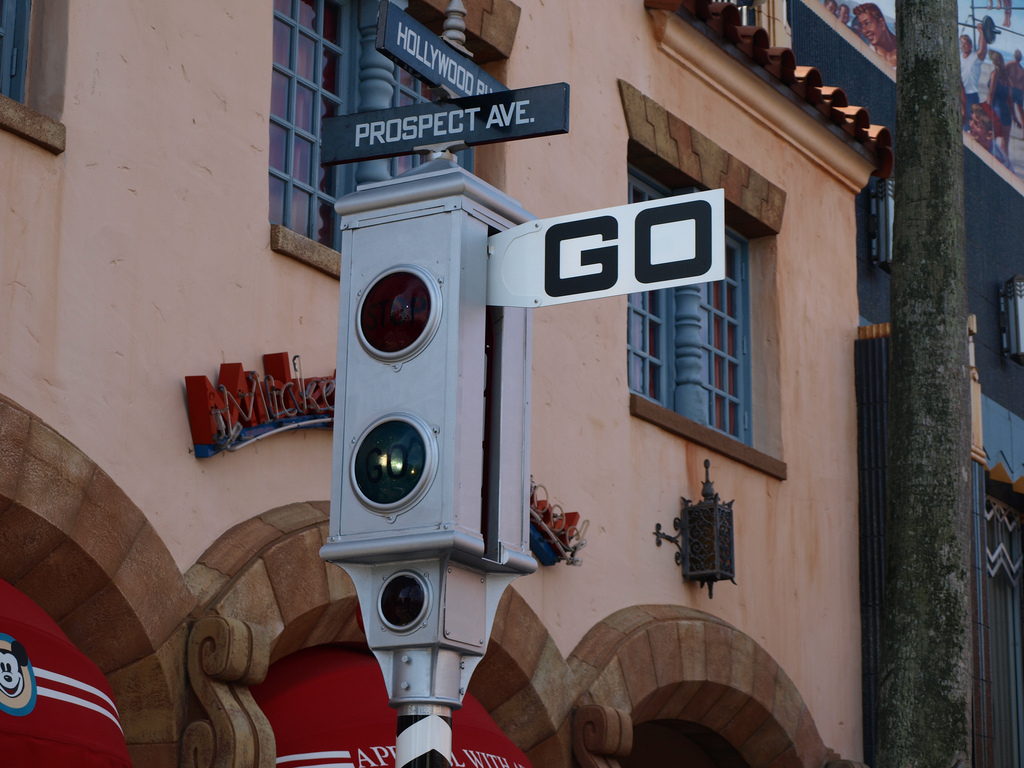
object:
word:
[547, 198, 712, 298]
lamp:
[652, 460, 737, 599]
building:
[0, 0, 893, 768]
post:
[318, 156, 546, 768]